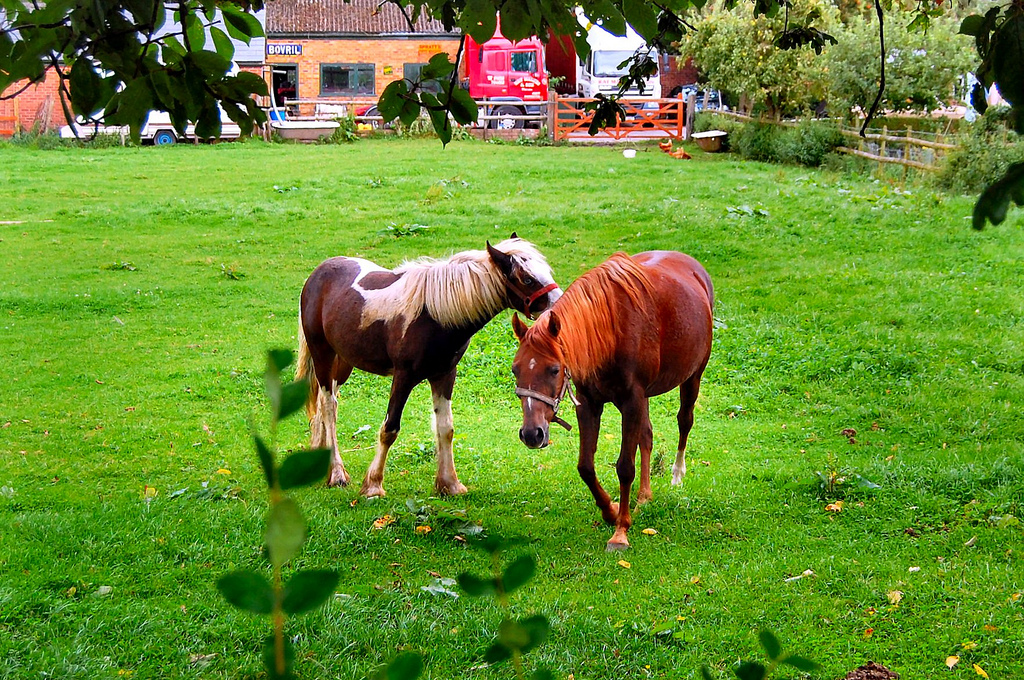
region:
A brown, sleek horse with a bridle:
[511, 241, 717, 561]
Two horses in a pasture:
[297, 235, 721, 556]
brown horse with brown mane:
[501, 232, 751, 569]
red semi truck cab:
[451, 11, 584, 142]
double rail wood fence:
[691, 62, 1011, 230]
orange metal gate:
[535, 83, 700, 148]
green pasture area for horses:
[239, 125, 767, 582]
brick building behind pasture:
[217, 0, 470, 131]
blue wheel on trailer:
[134, 112, 210, 179]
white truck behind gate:
[574, 20, 670, 107]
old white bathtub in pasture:
[259, 103, 368, 152]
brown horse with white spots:
[297, 228, 560, 508]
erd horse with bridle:
[509, 244, 712, 542]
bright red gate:
[550, 92, 684, 140]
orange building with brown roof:
[266, 0, 469, 115]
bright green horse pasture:
[6, 130, 1022, 674]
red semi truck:
[455, 14, 548, 125]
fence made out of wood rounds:
[678, 86, 966, 182]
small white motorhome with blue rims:
[57, 54, 248, 140]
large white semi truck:
[568, 2, 660, 113]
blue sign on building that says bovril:
[268, 43, 303, 57]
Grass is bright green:
[19, 318, 223, 436]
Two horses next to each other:
[283, 170, 762, 499]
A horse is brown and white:
[275, 240, 528, 472]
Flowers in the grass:
[790, 453, 1010, 665]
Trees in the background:
[684, 10, 962, 167]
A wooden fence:
[792, 92, 973, 201]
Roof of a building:
[247, 2, 447, 62]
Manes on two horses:
[407, 234, 674, 384]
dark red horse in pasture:
[509, 238, 721, 556]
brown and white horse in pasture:
[288, 238, 554, 495]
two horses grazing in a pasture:
[291, 216, 724, 570]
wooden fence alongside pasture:
[701, 92, 976, 188]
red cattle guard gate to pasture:
[543, 83, 702, 150]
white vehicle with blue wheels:
[59, 84, 252, 149]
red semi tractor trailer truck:
[461, 27, 548, 161]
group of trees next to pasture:
[694, 11, 963, 120]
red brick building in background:
[265, 5, 475, 151]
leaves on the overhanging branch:
[5, 5, 255, 129]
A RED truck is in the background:
[466, 32, 550, 132]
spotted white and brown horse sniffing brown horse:
[292, 227, 722, 553]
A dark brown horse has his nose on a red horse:
[293, 201, 625, 476]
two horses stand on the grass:
[291, 214, 722, 559]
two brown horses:
[279, 217, 729, 565]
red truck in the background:
[454, 27, 557, 127]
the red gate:
[545, 90, 688, 145]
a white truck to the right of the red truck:
[570, 24, 668, 136]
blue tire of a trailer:
[147, 119, 180, 148]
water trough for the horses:
[684, 122, 735, 154]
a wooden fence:
[697, 80, 1012, 194]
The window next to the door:
[310, 51, 372, 94]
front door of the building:
[264, 64, 306, 137]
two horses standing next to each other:
[294, 216, 727, 543]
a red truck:
[440, 32, 559, 124]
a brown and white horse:
[270, 212, 526, 497]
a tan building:
[256, 1, 462, 119]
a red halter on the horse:
[497, 263, 574, 311]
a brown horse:
[500, 236, 738, 544]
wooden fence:
[710, 107, 1008, 193]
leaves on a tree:
[0, 0, 311, 90]